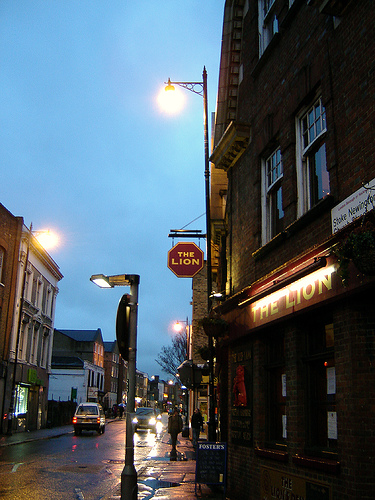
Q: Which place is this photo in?
A: It is at the restaurant.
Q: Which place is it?
A: It is a restaurant.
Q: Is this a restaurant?
A: Yes, it is a restaurant.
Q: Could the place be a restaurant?
A: Yes, it is a restaurant.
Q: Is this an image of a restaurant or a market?
A: It is showing a restaurant.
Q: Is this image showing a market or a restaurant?
A: It is showing a restaurant.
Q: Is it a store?
A: No, it is a restaurant.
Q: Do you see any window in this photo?
A: Yes, there is a window.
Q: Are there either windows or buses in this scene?
A: Yes, there is a window.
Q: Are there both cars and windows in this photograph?
A: Yes, there are both a window and a car.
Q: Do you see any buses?
A: No, there are no buses.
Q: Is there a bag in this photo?
A: No, there are no bags.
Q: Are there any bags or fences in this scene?
A: No, there are no bags or fences.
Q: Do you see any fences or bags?
A: No, there are no bags or fences.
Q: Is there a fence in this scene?
A: No, there are no fences.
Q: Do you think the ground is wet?
A: Yes, the ground is wet.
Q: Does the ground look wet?
A: Yes, the ground is wet.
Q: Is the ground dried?
A: No, the ground is wet.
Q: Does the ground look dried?
A: No, the ground is wet.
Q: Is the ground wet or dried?
A: The ground is wet.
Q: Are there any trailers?
A: No, there are no trailers.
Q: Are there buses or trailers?
A: No, there are no trailers or buses.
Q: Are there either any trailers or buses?
A: No, there are no trailers or buses.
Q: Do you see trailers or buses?
A: No, there are no trailers or buses.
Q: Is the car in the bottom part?
A: Yes, the car is in the bottom of the image.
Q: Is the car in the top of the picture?
A: No, the car is in the bottom of the image.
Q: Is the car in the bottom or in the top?
A: The car is in the bottom of the image.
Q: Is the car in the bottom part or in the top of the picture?
A: The car is in the bottom of the image.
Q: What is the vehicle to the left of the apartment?
A: The vehicle is a car.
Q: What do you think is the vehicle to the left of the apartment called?
A: The vehicle is a car.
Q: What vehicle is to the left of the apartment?
A: The vehicle is a car.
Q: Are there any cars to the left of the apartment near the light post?
A: Yes, there is a car to the left of the apartment.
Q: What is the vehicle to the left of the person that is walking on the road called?
A: The vehicle is a car.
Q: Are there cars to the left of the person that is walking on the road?
A: Yes, there is a car to the left of the person.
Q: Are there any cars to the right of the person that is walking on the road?
A: No, the car is to the left of the person.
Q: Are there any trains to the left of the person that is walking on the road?
A: No, there is a car to the left of the person.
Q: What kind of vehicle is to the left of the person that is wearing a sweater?
A: The vehicle is a car.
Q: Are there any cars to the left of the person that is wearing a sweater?
A: Yes, there is a car to the left of the person.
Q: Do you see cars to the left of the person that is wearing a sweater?
A: Yes, there is a car to the left of the person.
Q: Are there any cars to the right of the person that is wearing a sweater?
A: No, the car is to the left of the person.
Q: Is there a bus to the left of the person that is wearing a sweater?
A: No, there is a car to the left of the person.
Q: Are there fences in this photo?
A: No, there are no fences.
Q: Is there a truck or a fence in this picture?
A: No, there are no fences or trucks.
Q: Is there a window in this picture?
A: Yes, there is a window.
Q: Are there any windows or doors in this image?
A: Yes, there is a window.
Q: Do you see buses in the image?
A: No, there are no buses.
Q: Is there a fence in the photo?
A: No, there are no fences.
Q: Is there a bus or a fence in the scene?
A: No, there are no fences or buses.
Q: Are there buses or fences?
A: No, there are no fences or buses.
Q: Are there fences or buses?
A: No, there are no fences or buses.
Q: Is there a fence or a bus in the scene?
A: No, there are no fences or buses.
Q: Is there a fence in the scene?
A: No, there are no fences.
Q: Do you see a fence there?
A: No, there are no fences.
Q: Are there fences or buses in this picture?
A: No, there are no fences or buses.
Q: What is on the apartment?
A: The sign is on the apartment.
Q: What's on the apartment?
A: The sign is on the apartment.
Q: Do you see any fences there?
A: No, there are no fences.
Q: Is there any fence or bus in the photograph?
A: No, there are no fences or buses.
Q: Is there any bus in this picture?
A: No, there are no buses.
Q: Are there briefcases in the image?
A: No, there are no briefcases.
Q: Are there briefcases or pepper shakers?
A: No, there are no briefcases or pepper shakers.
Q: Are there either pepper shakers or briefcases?
A: No, there are no briefcases or pepper shakers.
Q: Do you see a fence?
A: No, there are no fences.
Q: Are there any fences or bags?
A: No, there are no fences or bags.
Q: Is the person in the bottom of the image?
A: Yes, the person is in the bottom of the image.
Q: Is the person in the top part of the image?
A: No, the person is in the bottom of the image.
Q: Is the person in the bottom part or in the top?
A: The person is in the bottom of the image.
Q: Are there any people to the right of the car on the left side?
A: Yes, there is a person to the right of the car.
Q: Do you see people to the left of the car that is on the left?
A: No, the person is to the right of the car.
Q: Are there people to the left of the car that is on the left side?
A: No, the person is to the right of the car.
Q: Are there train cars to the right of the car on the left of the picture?
A: No, there is a person to the right of the car.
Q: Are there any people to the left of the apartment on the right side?
A: Yes, there is a person to the left of the apartment.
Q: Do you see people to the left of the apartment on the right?
A: Yes, there is a person to the left of the apartment.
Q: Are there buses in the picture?
A: No, there are no buses.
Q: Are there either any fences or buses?
A: No, there are no buses or fences.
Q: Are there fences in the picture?
A: No, there are no fences.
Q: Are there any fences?
A: No, there are no fences.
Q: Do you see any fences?
A: No, there are no fences.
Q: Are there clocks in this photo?
A: No, there are no clocks.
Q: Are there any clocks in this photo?
A: No, there are no clocks.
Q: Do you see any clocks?
A: No, there are no clocks.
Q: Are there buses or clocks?
A: No, there are no clocks or buses.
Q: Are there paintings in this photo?
A: No, there are no paintings.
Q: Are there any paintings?
A: No, there are no paintings.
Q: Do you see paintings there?
A: No, there are no paintings.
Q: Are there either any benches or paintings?
A: No, there are no paintings or benches.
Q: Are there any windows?
A: Yes, there are windows.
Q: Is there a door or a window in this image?
A: Yes, there are windows.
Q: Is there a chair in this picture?
A: No, there are no chairs.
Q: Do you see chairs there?
A: No, there are no chairs.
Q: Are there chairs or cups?
A: No, there are no chairs or cups.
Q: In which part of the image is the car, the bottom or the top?
A: The car is in the bottom of the image.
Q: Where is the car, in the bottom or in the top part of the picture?
A: The car is in the bottom of the image.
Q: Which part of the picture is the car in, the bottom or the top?
A: The car is in the bottom of the image.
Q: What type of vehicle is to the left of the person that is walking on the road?
A: The vehicle is a car.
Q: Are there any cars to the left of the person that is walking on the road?
A: Yes, there is a car to the left of the person.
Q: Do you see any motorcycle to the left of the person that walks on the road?
A: No, there is a car to the left of the person.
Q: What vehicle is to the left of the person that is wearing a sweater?
A: The vehicle is a car.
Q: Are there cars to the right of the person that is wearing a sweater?
A: No, the car is to the left of the person.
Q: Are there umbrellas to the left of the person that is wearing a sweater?
A: No, there is a car to the left of the person.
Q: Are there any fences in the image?
A: No, there are no fences.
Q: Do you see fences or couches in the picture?
A: No, there are no fences or couches.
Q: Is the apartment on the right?
A: Yes, the apartment is on the right of the image.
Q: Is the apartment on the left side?
A: No, the apartment is on the right of the image.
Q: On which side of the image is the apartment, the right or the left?
A: The apartment is on the right of the image.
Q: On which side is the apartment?
A: The apartment is on the right of the image.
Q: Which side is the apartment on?
A: The apartment is on the right of the image.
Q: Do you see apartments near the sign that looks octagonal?
A: Yes, there is an apartment near the sign.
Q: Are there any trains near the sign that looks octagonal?
A: No, there is an apartment near the sign.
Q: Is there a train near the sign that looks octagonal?
A: No, there is an apartment near the sign.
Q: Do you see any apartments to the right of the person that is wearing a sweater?
A: Yes, there is an apartment to the right of the person.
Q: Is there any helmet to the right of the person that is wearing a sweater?
A: No, there is an apartment to the right of the person.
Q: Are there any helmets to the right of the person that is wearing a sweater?
A: No, there is an apartment to the right of the person.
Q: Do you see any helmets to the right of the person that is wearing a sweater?
A: No, there is an apartment to the right of the person.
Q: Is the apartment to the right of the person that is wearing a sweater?
A: Yes, the apartment is to the right of the person.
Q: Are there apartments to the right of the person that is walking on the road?
A: Yes, there is an apartment to the right of the person.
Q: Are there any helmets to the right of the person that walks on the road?
A: No, there is an apartment to the right of the person.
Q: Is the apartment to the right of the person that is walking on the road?
A: Yes, the apartment is to the right of the person.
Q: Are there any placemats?
A: No, there are no placemats.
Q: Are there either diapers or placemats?
A: No, there are no placemats or diapers.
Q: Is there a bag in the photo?
A: No, there are no bags.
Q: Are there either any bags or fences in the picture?
A: No, there are no bags or fences.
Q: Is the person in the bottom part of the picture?
A: Yes, the person is in the bottom of the image.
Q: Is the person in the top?
A: No, the person is in the bottom of the image.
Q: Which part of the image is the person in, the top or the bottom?
A: The person is in the bottom of the image.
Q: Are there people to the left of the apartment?
A: Yes, there is a person to the left of the apartment.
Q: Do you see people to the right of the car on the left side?
A: Yes, there is a person to the right of the car.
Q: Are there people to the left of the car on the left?
A: No, the person is to the right of the car.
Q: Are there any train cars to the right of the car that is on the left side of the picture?
A: No, there is a person to the right of the car.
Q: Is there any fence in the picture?
A: No, there are no fences.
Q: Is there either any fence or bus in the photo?
A: No, there are no fences or buses.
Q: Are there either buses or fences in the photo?
A: No, there are no fences or buses.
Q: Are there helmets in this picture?
A: No, there are no helmets.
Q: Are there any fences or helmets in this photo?
A: No, there are no helmets or fences.